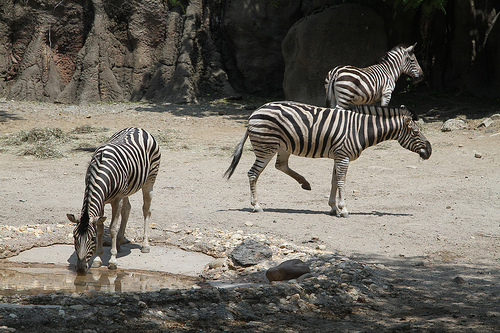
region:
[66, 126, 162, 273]
black and white zebra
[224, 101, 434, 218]
black and white zebra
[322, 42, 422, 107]
black and white zebra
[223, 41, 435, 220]
two black and white zebras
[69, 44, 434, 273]
three black and white zebras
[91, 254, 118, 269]
hooves of a zebra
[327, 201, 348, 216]
hooves of a zebra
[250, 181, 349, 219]
hooves of a zebra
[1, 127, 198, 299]
pond with zebra drinking from in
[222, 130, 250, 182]
tail of a zebra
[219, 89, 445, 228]
Zebra raise left back leg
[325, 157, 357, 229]
Front legs of zebra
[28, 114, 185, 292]
Zebra is drinking water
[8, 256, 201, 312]
Paddle of water in zebras pen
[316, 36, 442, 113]
Zebra is facing right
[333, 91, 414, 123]
Mane of zebra is white and black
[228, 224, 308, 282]
Stones next to water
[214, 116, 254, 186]
Tail of zebra is long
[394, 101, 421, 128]
Ears of zebra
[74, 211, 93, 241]
Mane of zebra is black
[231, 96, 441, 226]
a zebra has on of his legs elevated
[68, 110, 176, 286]
a zebra drinks from a watering hole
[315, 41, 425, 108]
zebra in the back is facing away from camera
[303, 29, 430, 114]
zebra walking toward the shade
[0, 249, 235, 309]
a watering hole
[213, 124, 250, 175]
tail of zebra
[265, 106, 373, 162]
zebra has stripes on its side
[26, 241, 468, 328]
the tree casts shade near a watering hole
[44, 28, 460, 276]
a trio of zebras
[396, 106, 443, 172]
head of zebra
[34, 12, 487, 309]
Three zebras in their habitat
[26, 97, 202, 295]
Zebra drinking water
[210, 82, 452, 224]
Zebra standing on three legs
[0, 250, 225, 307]
Water hole for the zebras to drink the water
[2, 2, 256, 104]
Rock walls in the background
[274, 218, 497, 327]
Dirt covered ground in the zebra's area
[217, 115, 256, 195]
Zebra's black tail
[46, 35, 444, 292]
Three black and white striped zebras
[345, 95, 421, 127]
Zebra's black and white mane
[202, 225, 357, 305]
Rocks on the ground near the water hole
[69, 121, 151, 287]
Zebra head down drink water.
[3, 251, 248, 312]
small puddle provides water animals.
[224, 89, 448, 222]
Pain left rear leg lifts up.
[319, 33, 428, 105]
Moving off to cooler area.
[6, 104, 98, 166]
Sparse patches green grass.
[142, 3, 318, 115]
Shadow predicts cooler space.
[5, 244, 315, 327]
Watering hole rocky rim.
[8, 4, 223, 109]
Rock formation eons old.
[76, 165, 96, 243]
Short black coarse mane neck.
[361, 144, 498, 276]
Ground packed down sandy earth.